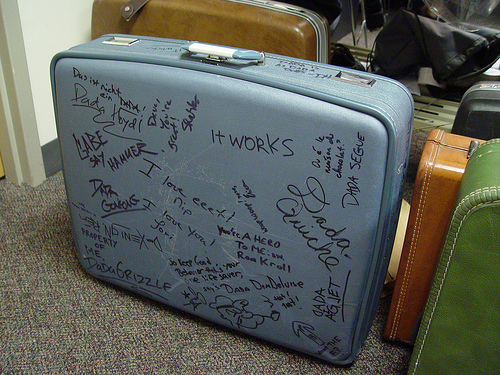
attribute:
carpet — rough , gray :
[9, 180, 405, 372]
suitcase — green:
[408, 135, 498, 374]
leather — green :
[458, 214, 496, 288]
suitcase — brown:
[89, 1, 353, 76]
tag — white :
[184, 37, 246, 77]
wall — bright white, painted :
[19, 0, 93, 145]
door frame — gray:
[2, 0, 47, 184]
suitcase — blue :
[66, 42, 406, 297]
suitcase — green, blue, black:
[48, 14, 428, 371]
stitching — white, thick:
[386, 125, 446, 355]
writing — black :
[205, 119, 297, 176]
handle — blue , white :
[180, 40, 268, 64]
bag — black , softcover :
[56, 19, 434, 361]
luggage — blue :
[49, 30, 414, 366]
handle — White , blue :
[184, 39, 263, 64]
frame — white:
[0, 63, 46, 183]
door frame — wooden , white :
[0, 3, 43, 189]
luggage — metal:
[445, 79, 498, 143]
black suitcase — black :
[447, 80, 499, 140]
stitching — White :
[386, 170, 440, 352]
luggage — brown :
[385, 126, 496, 348]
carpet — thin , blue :
[0, 63, 421, 372]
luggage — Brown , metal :
[76, 3, 325, 79]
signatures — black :
[56, 63, 365, 364]